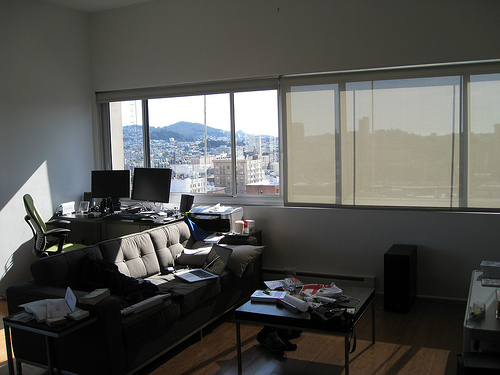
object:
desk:
[55, 202, 187, 244]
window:
[107, 60, 500, 209]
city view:
[122, 91, 281, 199]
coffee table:
[234, 275, 378, 374]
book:
[78, 287, 110, 305]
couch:
[4, 218, 266, 369]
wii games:
[480, 260, 500, 287]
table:
[462, 269, 500, 373]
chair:
[22, 193, 89, 259]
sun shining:
[0, 152, 237, 288]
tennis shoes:
[257, 323, 303, 353]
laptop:
[174, 244, 232, 283]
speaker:
[383, 243, 418, 313]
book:
[250, 289, 287, 302]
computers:
[92, 170, 130, 213]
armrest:
[43, 218, 72, 236]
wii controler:
[308, 296, 338, 304]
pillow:
[204, 244, 266, 277]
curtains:
[280, 57, 500, 211]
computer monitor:
[91, 169, 130, 198]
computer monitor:
[131, 168, 173, 203]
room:
[0, 0, 500, 374]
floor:
[0, 293, 465, 375]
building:
[122, 123, 280, 196]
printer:
[187, 204, 244, 234]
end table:
[3, 304, 100, 375]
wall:
[0, 1, 499, 297]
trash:
[250, 266, 359, 321]